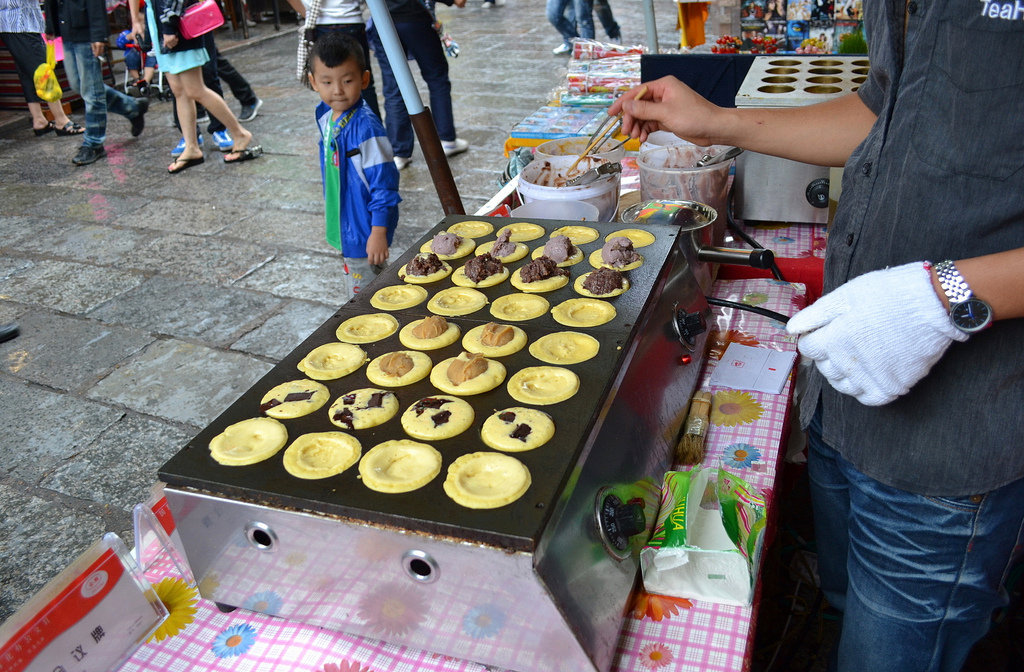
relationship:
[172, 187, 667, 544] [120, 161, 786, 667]
food on griddle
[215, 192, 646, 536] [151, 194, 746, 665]
food on griddle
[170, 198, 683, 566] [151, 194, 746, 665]
food on griddle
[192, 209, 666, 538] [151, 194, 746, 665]
food on griddle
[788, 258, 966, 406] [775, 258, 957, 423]
glove on hand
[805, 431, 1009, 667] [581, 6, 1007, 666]
jeans on man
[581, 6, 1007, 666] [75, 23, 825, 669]
man behind table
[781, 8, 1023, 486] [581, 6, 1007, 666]
shirt on man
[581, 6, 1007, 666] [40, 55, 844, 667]
man behind table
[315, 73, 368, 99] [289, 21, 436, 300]
eyes of boy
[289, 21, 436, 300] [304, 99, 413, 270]
boy in jacket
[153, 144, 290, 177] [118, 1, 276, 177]
sandals on lady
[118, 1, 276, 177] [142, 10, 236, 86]
lady wearing skirt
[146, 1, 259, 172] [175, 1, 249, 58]
lady wearing purse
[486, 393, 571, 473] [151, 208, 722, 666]
cookie being cooked on grill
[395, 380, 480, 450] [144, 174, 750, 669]
cookie being cooked on grill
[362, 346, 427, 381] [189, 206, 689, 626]
cookie cooked on grill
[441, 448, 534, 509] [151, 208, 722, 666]
cookie being cooked on grill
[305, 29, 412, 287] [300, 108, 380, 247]
boy with shirt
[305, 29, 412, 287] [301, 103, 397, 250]
boy wearing jacket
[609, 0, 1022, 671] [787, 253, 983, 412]
man has hand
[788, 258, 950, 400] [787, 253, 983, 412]
glove on hand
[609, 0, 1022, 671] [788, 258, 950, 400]
man wearing glove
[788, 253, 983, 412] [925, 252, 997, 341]
hand wearing wrist watch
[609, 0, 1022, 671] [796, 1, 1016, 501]
man wearing shirt